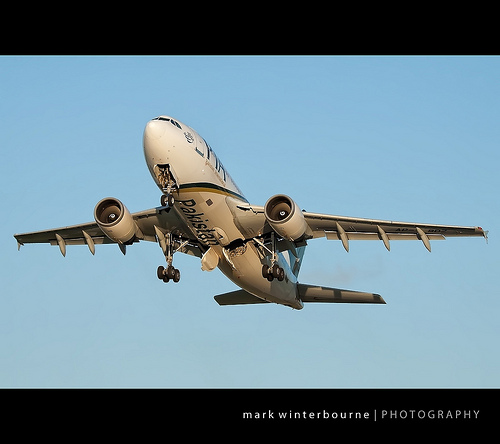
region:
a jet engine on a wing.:
[253, 191, 323, 252]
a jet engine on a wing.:
[224, 191, 492, 254]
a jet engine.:
[88, 185, 136, 260]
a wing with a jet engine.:
[0, 186, 197, 281]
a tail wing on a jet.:
[192, 266, 395, 329]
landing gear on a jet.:
[148, 257, 191, 287]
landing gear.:
[255, 256, 295, 291]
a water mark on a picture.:
[232, 401, 489, 439]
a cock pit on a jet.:
[128, 106, 212, 176]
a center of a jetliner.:
[134, 107, 306, 308]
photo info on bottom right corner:
[220, 402, 489, 437]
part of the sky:
[272, 82, 450, 157]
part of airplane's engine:
[247, 194, 306, 239]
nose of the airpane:
[137, 117, 170, 144]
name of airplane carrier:
[170, 199, 220, 248]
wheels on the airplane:
[153, 259, 185, 284]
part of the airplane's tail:
[307, 278, 376, 311]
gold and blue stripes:
[190, 182, 231, 197]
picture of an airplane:
[12, 111, 482, 326]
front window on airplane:
[153, 112, 182, 125]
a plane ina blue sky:
[11, 94, 491, 325]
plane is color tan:
[5, 102, 496, 342]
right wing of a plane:
[262, 187, 492, 262]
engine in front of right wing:
[256, 188, 313, 246]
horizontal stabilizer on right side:
[294, 271, 391, 313]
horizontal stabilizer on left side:
[207, 282, 259, 312]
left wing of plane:
[11, 196, 161, 261]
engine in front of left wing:
[85, 191, 145, 260]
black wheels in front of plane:
[151, 183, 185, 215]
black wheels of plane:
[147, 257, 288, 292]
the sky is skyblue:
[276, 90, 456, 180]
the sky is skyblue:
[345, 155, 390, 203]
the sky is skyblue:
[380, 337, 425, 378]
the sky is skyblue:
[389, 357, 414, 377]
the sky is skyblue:
[372, 307, 460, 412]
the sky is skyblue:
[375, 272, 440, 359]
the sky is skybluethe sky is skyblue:
[420, 288, 427, 383]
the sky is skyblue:
[385, 317, 426, 365]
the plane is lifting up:
[49, 87, 459, 259]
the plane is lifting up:
[105, 87, 360, 398]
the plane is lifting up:
[123, 104, 314, 289]